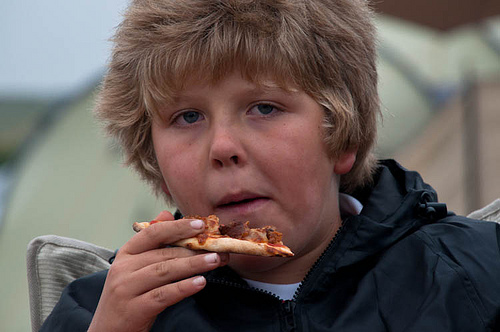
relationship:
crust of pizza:
[132, 221, 299, 258] [129, 212, 298, 260]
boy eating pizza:
[34, 1, 498, 330] [129, 212, 298, 260]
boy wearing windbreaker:
[34, 1, 498, 330] [38, 158, 488, 329]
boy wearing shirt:
[34, 1, 498, 330] [239, 192, 363, 302]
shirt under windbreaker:
[239, 192, 363, 302] [38, 158, 488, 329]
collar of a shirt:
[337, 189, 363, 218] [239, 192, 363, 302]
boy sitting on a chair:
[34, 1, 498, 330] [23, 195, 496, 327]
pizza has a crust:
[129, 212, 298, 260] [132, 221, 299, 258]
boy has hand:
[34, 1, 498, 330] [81, 216, 231, 330]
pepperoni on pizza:
[146, 217, 159, 226] [129, 212, 298, 260]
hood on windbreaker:
[172, 158, 449, 225] [38, 158, 488, 329]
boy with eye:
[34, 1, 498, 330] [245, 99, 289, 120]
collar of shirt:
[337, 189, 363, 218] [239, 192, 363, 302]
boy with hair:
[34, 1, 498, 330] [87, 2, 388, 206]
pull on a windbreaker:
[280, 297, 299, 330] [38, 158, 488, 329]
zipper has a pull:
[192, 211, 370, 330] [280, 297, 299, 330]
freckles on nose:
[210, 131, 237, 144] [205, 113, 250, 169]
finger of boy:
[122, 217, 207, 253] [34, 1, 498, 330]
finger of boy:
[127, 246, 231, 268] [34, 1, 498, 330]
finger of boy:
[130, 275, 207, 308] [34, 1, 498, 330]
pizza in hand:
[129, 212, 298, 260] [81, 216, 231, 330]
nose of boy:
[205, 113, 250, 169] [34, 1, 498, 330]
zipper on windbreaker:
[192, 211, 370, 330] [38, 158, 488, 329]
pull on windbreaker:
[280, 297, 299, 330] [38, 158, 488, 329]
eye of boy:
[163, 105, 205, 129] [34, 1, 498, 330]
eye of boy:
[245, 99, 289, 120] [34, 1, 498, 330]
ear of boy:
[333, 98, 361, 175] [34, 1, 498, 330]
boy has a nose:
[34, 1, 498, 330] [205, 113, 250, 169]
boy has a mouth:
[34, 1, 498, 330] [212, 189, 275, 219]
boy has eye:
[34, 1, 498, 330] [245, 99, 289, 120]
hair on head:
[87, 2, 388, 206] [87, 0, 386, 276]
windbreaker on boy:
[38, 158, 488, 329] [34, 1, 498, 330]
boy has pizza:
[34, 1, 498, 330] [129, 212, 298, 260]